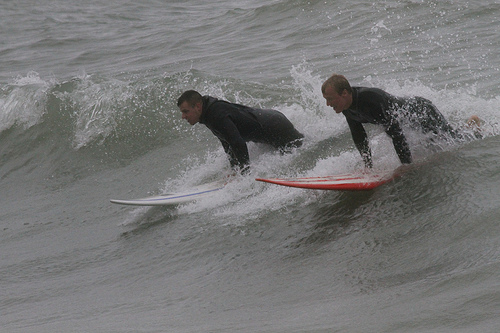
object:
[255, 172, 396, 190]
surfboard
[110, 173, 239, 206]
surfboard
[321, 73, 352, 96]
hair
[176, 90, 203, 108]
hair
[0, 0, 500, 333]
ocean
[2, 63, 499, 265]
wave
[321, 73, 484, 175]
surfer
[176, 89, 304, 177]
man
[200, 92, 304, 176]
wet suit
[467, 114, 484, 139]
foot